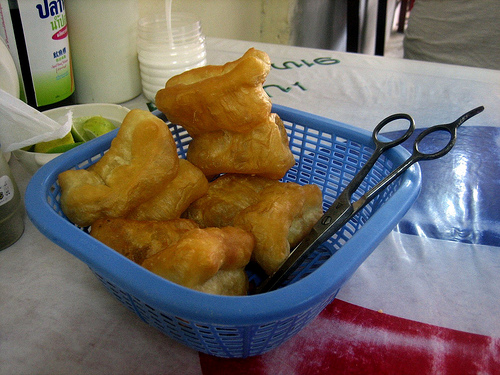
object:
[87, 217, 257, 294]
dough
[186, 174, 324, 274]
dough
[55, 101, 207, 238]
dough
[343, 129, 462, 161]
person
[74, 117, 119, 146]
wedge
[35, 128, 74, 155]
wedge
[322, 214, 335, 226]
screw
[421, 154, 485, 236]
reflection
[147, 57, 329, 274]
food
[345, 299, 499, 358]
cloth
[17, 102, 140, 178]
bowl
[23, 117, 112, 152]
limes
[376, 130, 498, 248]
plastic tablecloth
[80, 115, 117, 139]
limes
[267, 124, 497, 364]
circle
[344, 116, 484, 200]
handle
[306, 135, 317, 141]
holes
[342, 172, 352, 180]
holes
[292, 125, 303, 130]
holes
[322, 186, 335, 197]
holes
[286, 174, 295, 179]
holes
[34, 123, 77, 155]
lime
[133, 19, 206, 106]
jar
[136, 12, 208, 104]
bottle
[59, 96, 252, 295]
food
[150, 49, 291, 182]
doughnut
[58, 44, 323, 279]
food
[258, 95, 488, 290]
black shirt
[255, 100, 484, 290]
scissor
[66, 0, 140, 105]
bottle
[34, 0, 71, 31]
writing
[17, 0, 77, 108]
label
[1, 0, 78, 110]
bottle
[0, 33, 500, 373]
table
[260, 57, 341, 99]
writing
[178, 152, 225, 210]
pastries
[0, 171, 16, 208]
symbol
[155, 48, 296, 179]
dough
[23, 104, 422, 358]
basket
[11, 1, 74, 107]
vanilla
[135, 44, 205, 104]
cream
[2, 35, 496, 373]
table cloth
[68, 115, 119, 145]
slice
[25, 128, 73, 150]
slice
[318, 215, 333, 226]
bolt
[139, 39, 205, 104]
milk